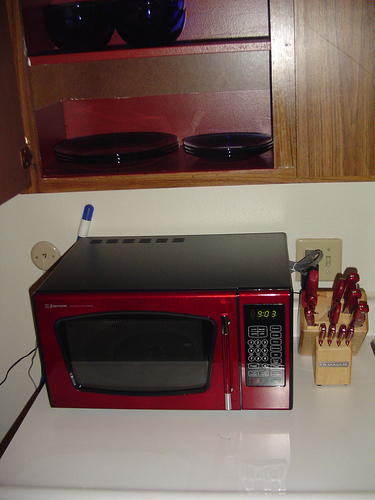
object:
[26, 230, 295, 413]
microwave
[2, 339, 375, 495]
counter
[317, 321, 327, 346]
knives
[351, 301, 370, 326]
handle of knife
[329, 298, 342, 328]
handle of knife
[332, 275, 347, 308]
handle of knife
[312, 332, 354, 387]
knife holder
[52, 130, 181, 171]
plates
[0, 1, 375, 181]
cabinet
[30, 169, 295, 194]
shelf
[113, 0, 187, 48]
dishes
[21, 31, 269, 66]
shelf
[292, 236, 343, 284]
light switch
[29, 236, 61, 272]
telephone outlet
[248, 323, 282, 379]
control panel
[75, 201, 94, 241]
handle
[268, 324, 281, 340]
buttons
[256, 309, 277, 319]
9:03 readout